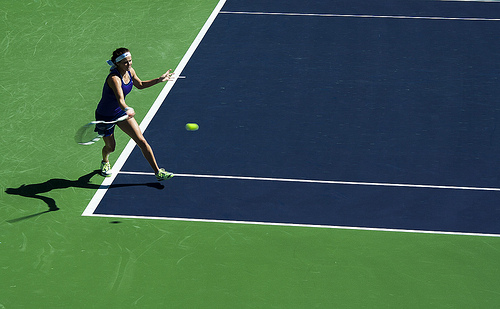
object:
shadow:
[6, 172, 165, 225]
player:
[93, 45, 173, 179]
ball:
[184, 121, 201, 131]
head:
[106, 47, 134, 70]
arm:
[129, 70, 179, 88]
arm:
[110, 78, 134, 120]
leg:
[114, 114, 169, 178]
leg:
[101, 125, 118, 174]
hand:
[124, 107, 138, 118]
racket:
[72, 115, 134, 147]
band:
[109, 52, 134, 62]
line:
[217, 10, 500, 22]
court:
[3, 3, 499, 308]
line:
[114, 170, 498, 192]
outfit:
[96, 75, 137, 134]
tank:
[103, 72, 139, 107]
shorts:
[95, 113, 130, 133]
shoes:
[98, 159, 116, 179]